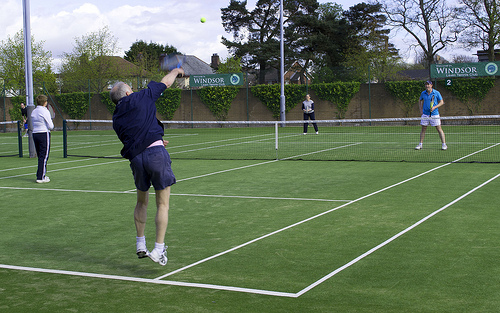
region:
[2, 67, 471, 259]
the men are playing tennis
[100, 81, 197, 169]
man's shirt is blue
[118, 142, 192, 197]
men's shorts are blue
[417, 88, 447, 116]
man's shirt is blue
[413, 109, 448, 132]
man's shorts are white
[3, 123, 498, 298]
white lines on court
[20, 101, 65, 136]
woman's shirt is white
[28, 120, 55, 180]
woman's shorts are black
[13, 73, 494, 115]
grass on the wall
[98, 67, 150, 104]
man's hair is gray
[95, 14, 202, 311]
Tennis player jumps in the air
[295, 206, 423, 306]
White paint on the grass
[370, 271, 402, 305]
The grass is very short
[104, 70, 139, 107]
Man is going bald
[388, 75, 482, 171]
Man is standing in a wide leg stance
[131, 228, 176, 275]
Man wearing tennis shoes and socks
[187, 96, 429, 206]
Net inbetween the tennis court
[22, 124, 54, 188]
Woman wearing pants with stripes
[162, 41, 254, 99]
Sign on the side of court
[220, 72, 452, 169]
Wall behind the court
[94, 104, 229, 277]
this is a man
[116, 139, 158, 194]
the man is a tennis player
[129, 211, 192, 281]
these are tennis shoes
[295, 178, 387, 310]
this is a tennis court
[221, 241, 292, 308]
the court is green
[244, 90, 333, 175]
this is a tennis net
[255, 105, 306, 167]
the net is black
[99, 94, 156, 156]
the shirt is blue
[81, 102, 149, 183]
the shorts are blue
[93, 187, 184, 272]
these are some socks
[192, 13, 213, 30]
tennis ball in mid air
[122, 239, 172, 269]
pair of white and blue sneakers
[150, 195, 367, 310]
white lines drawn on green field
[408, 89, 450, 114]
bleu short sleeve shirt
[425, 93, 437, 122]
tennis racket in person's hand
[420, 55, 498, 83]
green banner on top of stone wall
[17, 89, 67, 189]
woman standing on tennis court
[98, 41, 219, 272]
man jumping in air and swinging tennis racket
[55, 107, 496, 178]
long tennis net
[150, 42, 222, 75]
house roof beyond stone wall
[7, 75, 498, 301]
Tennis court with 4 people playing doubles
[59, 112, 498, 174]
Net on the foreground tennis court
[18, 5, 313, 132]
Light poles around the tennis courts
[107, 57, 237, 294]
Man serving the ball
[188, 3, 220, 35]
Tennis ball in play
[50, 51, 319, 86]
Houses behind the tennis courts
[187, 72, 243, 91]
A sign for the tennis courts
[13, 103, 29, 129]
A person playing a game on another tennis court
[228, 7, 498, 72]
Trees behind the tennis courts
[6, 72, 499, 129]
Brick wall marking the back of the tennis courts